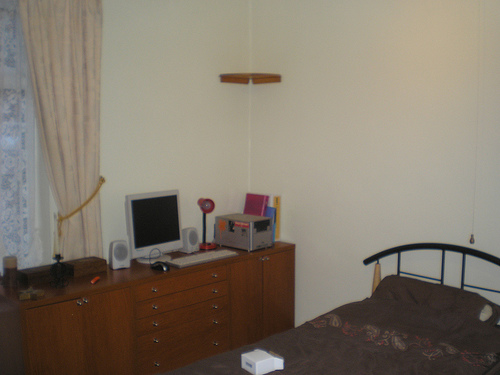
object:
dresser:
[0, 241, 295, 375]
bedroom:
[0, 0, 500, 375]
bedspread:
[165, 273, 500, 375]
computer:
[124, 188, 239, 273]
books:
[242, 193, 270, 217]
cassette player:
[213, 212, 273, 254]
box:
[239, 348, 286, 375]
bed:
[152, 242, 500, 375]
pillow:
[370, 274, 492, 324]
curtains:
[16, 0, 99, 259]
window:
[0, 0, 48, 269]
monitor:
[124, 189, 185, 265]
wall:
[282, 0, 499, 238]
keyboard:
[166, 250, 238, 269]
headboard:
[361, 242, 500, 304]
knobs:
[152, 289, 157, 293]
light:
[197, 197, 218, 250]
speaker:
[182, 227, 201, 253]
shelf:
[219, 72, 282, 84]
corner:
[245, 4, 253, 192]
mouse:
[150, 260, 170, 271]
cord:
[47, 179, 119, 222]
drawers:
[134, 264, 229, 305]